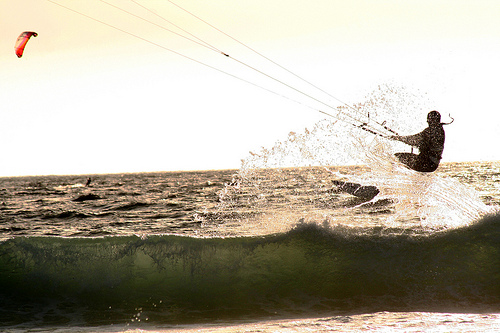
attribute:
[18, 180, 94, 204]
water — part, spraying, splashing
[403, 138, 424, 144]
elbow — part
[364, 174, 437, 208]
splash — part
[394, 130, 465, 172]
costume — part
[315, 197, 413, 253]
wave — edge, tall, rising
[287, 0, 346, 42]
cloud — part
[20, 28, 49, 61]
kite — flying, red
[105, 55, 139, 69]
sky — white, cloudy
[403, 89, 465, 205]
man — surfing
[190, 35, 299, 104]
cord — black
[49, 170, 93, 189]
bird — floating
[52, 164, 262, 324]
ocean — vast